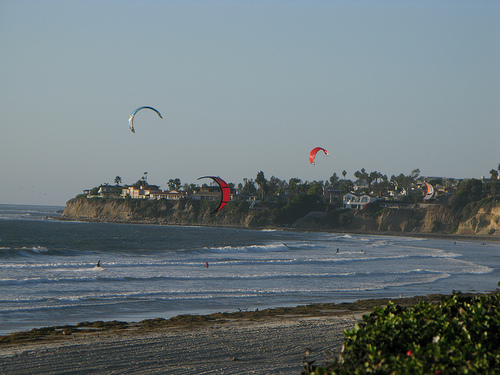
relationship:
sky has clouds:
[0, 2, 498, 209] [338, 54, 423, 109]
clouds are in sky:
[401, 47, 469, 92] [0, 2, 498, 209]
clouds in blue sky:
[363, 58, 447, 118] [0, 2, 499, 206]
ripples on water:
[21, 210, 476, 332] [0, 217, 498, 334]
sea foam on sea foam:
[201, 240, 291, 250] [201, 240, 291, 250]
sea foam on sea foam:
[3, 257, 119, 276] [201, 240, 291, 250]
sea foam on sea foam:
[259, 227, 279, 236] [201, 240, 291, 250]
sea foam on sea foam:
[4, 272, 459, 304] [201, 240, 291, 250]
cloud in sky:
[14, 26, 45, 62] [0, 2, 498, 209]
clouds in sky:
[313, 78, 423, 148] [5, 2, 497, 166]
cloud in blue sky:
[362, 102, 459, 146] [345, 25, 480, 110]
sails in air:
[109, 90, 349, 232] [22, 20, 459, 173]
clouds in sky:
[390, 13, 462, 84] [46, 23, 482, 167]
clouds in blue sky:
[398, 95, 428, 129] [0, 2, 499, 206]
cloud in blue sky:
[358, 111, 457, 161] [0, 2, 499, 206]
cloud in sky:
[357, 119, 475, 170] [0, 2, 498, 209]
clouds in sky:
[15, 88, 437, 188] [5, 2, 497, 166]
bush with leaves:
[328, 285, 495, 367] [362, 314, 484, 346]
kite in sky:
[200, 177, 231, 217] [0, 2, 498, 209]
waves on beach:
[233, 237, 492, 286] [13, 244, 498, 374]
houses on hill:
[85, 174, 488, 209] [62, 172, 498, 236]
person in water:
[89, 252, 109, 274] [0, 239, 494, 325]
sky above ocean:
[0, 2, 498, 209] [0, 200, 496, 333]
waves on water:
[243, 247, 325, 306] [12, 218, 459, 301]